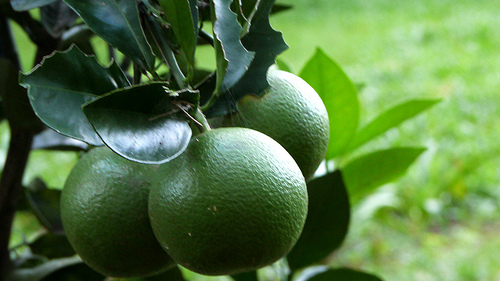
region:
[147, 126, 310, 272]
Lime hanging from a branch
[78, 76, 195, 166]
Dark green leaf on a lime stem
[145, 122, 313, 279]
Round green lime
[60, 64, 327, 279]
Three limes hanging on a branch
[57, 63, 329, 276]
Three limes on a tree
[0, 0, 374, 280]
Lime tree with limes and leaves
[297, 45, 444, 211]
Three lighter green leaves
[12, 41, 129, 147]
Ridged dark green leaf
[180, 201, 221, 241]
Imperfections on a lime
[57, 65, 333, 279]
Three limes in a bunch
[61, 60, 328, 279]
Bunch of green limes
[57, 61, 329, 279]
Three green limes on a branch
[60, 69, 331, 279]
Three green limes on a tree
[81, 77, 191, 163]
Dark green lime stem leaf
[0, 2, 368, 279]
Lime tree with dark leaves and limes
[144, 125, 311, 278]
One round green lime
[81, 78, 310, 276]
Lime and leaf on a branch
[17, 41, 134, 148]
Dark green ridged leaf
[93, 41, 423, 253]
view is at an orchids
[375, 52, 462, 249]
plants are seen at the background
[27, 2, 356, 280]
he plant is of an orange tree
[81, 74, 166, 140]
the leafs are dark green incolor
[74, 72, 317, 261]
the fuits are on branch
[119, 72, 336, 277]
the fruits grow in bunches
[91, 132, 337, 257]
the oranges are not rippen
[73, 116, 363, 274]
oranges are green in color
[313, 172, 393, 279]
shadow is seen on ground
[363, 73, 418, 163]
part of the green plants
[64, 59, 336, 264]
bundle of fruit on a tree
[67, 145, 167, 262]
fruit on the left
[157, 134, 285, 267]
fruit in the center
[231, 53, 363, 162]
fruit on the right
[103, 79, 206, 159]
dark leaf on the plant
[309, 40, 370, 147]
light leaf near the plant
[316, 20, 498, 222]
green lawn beneath the plant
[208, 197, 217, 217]
brown spot on fruit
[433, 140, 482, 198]
wild plants on the ground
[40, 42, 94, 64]
leaf edge that is jagged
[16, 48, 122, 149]
leaf on a plant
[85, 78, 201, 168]
leaf on a plant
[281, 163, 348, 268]
leaf on a plant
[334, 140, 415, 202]
leaf on a plant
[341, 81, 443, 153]
leaf on a plant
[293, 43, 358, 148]
leaf on a plant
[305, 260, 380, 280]
leaf on a plant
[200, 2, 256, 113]
leaf on a plant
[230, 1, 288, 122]
leaf on a plant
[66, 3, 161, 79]
leaf on a plant